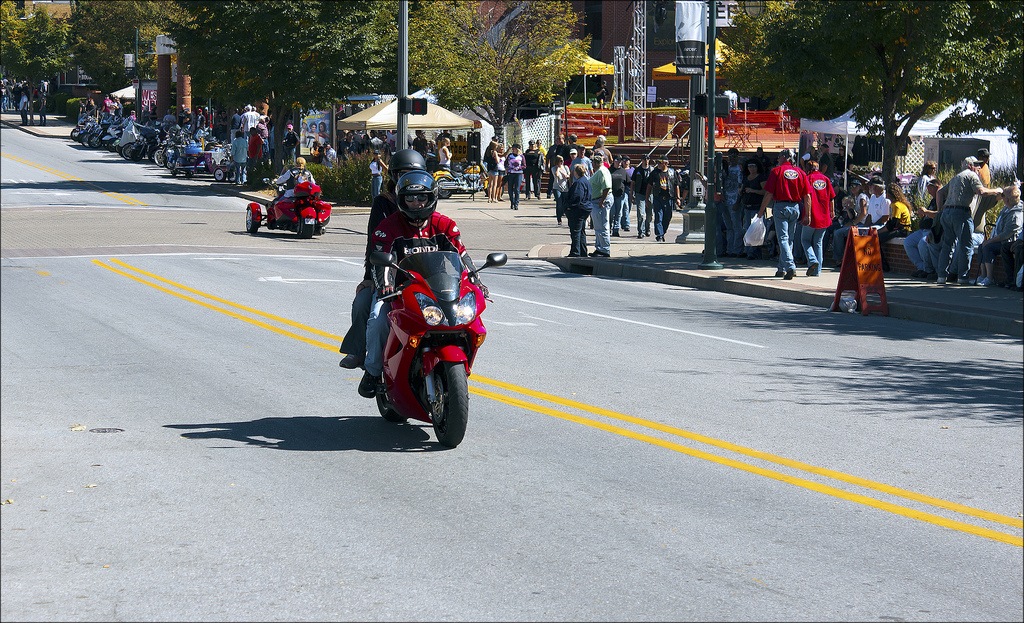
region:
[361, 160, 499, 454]
Man on a motorcycle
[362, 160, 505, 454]
Man is on a motorcycle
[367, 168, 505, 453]
Man on a red motorcycle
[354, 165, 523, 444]
Man is on a red motorcycle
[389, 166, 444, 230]
Man wearing a helmet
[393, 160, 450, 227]
Man is wearing a helmet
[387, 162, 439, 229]
Man wearing a black helmet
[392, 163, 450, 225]
Man is wearing a black helmet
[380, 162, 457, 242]
Man wearing a black motorcycle helmet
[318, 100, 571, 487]
they are riding a motorcycle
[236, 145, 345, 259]
this is a motor vehicle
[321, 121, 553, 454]
there are two people on the motorcycle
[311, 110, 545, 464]
both of them are wearing black helmets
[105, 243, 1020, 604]
this is a double yellow line in the street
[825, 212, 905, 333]
this is an orange street sign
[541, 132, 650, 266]
these two people are standing on the curb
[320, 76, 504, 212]
this is a gold canopy tent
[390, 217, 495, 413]
red bike on street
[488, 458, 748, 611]
road is light grey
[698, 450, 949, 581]
yellow lines on road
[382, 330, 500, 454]
black tire on bike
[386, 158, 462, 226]
man has black helmet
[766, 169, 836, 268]
men in red shirts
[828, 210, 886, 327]
orange sign near road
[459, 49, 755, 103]
yellow canopies on tents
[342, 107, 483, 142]
light brown canopy of tent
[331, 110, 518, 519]
two people on a red motorcycle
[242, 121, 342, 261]
a man on a three wheeled motorcycle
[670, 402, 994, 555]
two yellow lines on city street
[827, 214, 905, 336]
an orange parking marker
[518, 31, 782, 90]
two large yellow canopies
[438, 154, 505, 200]
a yellow motorcycle parked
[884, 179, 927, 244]
a person with long hair wearing a yellow shirt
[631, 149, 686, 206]
two men wearing motorcycle vests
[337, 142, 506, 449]
two people riding red motorcycle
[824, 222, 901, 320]
sign on side of street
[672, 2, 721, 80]
flag hanging on pole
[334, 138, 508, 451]
two people riding on a motorcycle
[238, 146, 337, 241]
person in red motorcycle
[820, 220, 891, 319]
foldable orange plastic sign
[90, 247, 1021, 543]
pair of yellow lines in the middle of road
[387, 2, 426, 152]
silver pole with crosswalk light fixture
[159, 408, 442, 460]
shadow cast on a road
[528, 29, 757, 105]
two yellow canopies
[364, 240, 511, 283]
two black sideview motorcycle mirrors